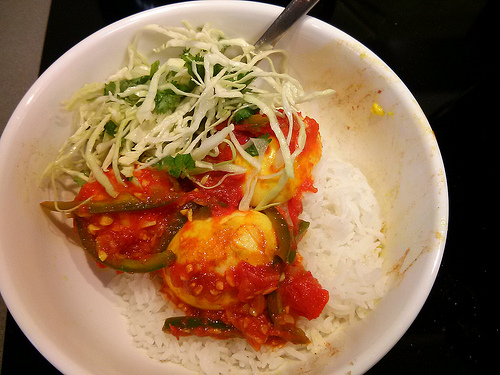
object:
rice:
[320, 210, 376, 284]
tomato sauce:
[278, 271, 329, 323]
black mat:
[455, 10, 499, 366]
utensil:
[242, 0, 319, 65]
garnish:
[37, 23, 336, 214]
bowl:
[0, 0, 449, 375]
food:
[38, 25, 337, 354]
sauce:
[73, 108, 330, 351]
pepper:
[119, 251, 173, 273]